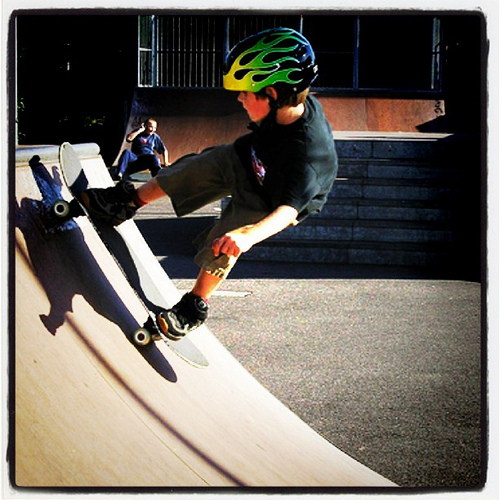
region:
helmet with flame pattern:
[215, 25, 321, 96]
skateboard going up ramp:
[37, 150, 194, 350]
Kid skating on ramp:
[27, 17, 353, 359]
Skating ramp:
[12, 141, 397, 481]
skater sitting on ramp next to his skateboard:
[115, 110, 175, 210]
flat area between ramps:
[225, 260, 475, 485]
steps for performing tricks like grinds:
[335, 135, 480, 265]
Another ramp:
[126, 90, 436, 130]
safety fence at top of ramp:
[136, 10, 439, 90]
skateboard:
[114, 167, 165, 183]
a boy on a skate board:
[0, 25, 348, 362]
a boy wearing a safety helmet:
[186, 19, 329, 101]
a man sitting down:
[101, 113, 173, 176]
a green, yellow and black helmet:
[200, 27, 332, 99]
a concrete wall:
[239, 127, 435, 265]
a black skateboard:
[53, 135, 205, 375]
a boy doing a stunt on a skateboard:
[33, 30, 340, 354]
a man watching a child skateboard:
[126, 17, 357, 322]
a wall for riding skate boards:
[17, 135, 345, 469]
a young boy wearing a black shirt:
[16, 20, 365, 345]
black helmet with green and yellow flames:
[212, 22, 324, 100]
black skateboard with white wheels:
[49, 135, 214, 375]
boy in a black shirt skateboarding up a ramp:
[38, 17, 353, 382]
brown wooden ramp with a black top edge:
[14, 125, 411, 488]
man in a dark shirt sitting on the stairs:
[110, 107, 173, 186]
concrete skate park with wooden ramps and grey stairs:
[14, 10, 486, 492]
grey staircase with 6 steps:
[336, 127, 444, 282]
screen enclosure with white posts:
[130, 14, 481, 96]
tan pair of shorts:
[157, 138, 277, 277]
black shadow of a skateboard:
[14, 151, 179, 392]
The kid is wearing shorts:
[134, 141, 299, 292]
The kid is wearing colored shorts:
[141, 142, 269, 285]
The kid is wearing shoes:
[68, 146, 238, 381]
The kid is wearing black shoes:
[70, 151, 220, 362]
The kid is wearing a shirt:
[230, 112, 365, 247]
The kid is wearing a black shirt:
[230, 110, 350, 226]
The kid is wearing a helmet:
[223, 20, 341, 105]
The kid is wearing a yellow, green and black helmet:
[206, 20, 361, 122]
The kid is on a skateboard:
[20, 128, 217, 362]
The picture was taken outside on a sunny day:
[19, 21, 479, 494]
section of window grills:
[180, 44, 202, 64]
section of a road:
[377, 332, 395, 388]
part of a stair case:
[412, 145, 422, 226]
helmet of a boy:
[272, 44, 307, 68]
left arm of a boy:
[266, 207, 284, 235]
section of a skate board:
[126, 248, 141, 275]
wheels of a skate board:
[138, 331, 146, 344]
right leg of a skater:
[133, 177, 168, 199]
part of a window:
[145, 27, 151, 39]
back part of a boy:
[318, 132, 330, 160]